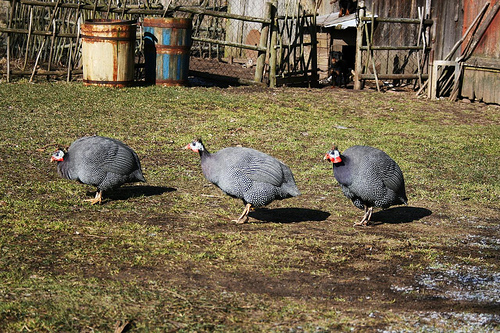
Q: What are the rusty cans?
A: Trash cans.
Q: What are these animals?
A: Turkeys.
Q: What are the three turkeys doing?
A: Walking together.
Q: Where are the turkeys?
A: On a farm.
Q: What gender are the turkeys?
A: Males.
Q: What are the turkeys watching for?
A: Predators.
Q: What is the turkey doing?
A: Walking slowly.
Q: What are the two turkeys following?
A: Another turkey.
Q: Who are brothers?
A: The turkeys.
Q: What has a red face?
A: The ginney.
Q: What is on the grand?
A: Grass and mud.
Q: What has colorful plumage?
A: The turkeys.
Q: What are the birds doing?
A: Following each other.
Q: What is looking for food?
A: The birds.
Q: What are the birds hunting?
A: FOR worms.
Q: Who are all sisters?
A: The birds.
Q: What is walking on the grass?
A: Birds.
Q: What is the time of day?
A: Birds are out in the daytime.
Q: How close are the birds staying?
A: Very close together.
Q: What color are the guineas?
A: Gray and white.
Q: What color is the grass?
A: Green.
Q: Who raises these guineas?
A: The photographer.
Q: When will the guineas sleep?
A: During the evening and night.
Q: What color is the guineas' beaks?
A: Yellow.